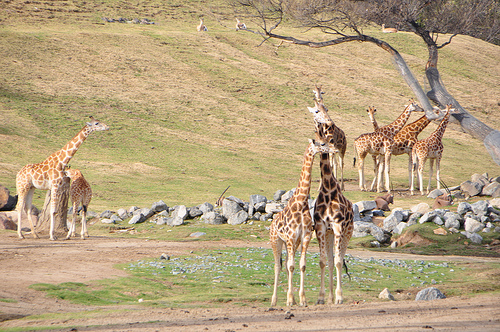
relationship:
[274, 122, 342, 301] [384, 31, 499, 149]
giraffes by tree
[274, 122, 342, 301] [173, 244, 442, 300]
giraffes in grass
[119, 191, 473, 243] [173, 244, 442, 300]
rocks in grass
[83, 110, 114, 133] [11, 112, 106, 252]
head of giraffe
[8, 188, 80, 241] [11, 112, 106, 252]
legs of giraffe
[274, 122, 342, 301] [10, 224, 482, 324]
giraffes in forefront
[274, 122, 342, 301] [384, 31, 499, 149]
giraffes near tree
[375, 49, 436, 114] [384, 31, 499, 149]
branch of tree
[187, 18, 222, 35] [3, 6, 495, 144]
animal in distance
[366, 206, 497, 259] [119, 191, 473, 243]
moss on rocks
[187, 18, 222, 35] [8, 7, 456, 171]
animal on hill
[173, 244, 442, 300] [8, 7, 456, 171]
grass on hill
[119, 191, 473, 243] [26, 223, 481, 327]
rocks on ground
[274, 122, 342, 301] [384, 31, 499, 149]
giraffes under tree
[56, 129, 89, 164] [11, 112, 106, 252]
neck of giraffe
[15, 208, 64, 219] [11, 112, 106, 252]
knees of giraffe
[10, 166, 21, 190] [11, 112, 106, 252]
tail of giraffe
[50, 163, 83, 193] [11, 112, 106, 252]
chest of giraffe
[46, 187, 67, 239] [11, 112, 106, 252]
leg of giraffe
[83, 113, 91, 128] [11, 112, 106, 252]
ear of giraffe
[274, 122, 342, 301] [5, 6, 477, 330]
giraffes in wild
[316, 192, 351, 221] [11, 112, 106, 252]
spots on giraffe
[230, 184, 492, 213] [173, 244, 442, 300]
stones on grass